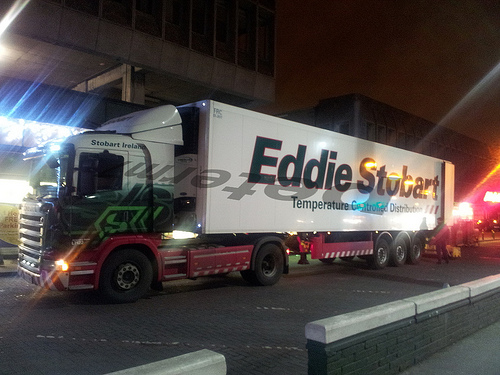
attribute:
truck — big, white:
[31, 97, 471, 289]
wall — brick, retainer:
[312, 278, 469, 374]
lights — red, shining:
[33, 252, 154, 284]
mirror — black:
[59, 156, 108, 209]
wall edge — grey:
[305, 278, 486, 331]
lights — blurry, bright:
[438, 76, 496, 259]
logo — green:
[69, 189, 166, 241]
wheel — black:
[410, 235, 424, 263]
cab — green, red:
[0, 130, 172, 309]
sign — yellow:
[1, 205, 27, 258]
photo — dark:
[0, 11, 492, 330]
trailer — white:
[205, 99, 465, 248]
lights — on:
[28, 244, 96, 286]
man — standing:
[408, 194, 471, 268]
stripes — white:
[322, 247, 376, 260]